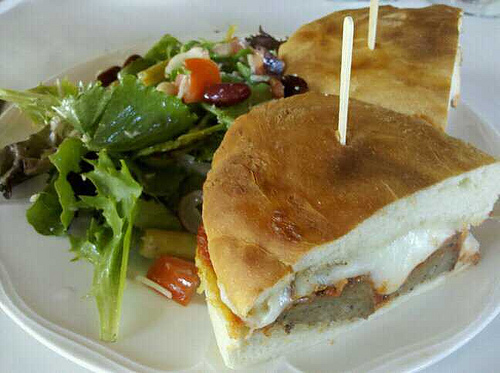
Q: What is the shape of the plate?
A: Circular.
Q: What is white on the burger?
A: Cheese.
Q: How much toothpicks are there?
A: Two.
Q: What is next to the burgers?
A: A salad.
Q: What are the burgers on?
A: A white plate.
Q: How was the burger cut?
A: In half.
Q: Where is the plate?
A: On a white surface.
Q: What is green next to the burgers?
A: Lettuce.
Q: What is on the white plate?
A: A burger and salad.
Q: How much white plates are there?
A: One.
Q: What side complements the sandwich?
A: A salad.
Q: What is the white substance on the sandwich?
A: Cheese.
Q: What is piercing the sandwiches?
A: Toothpicks.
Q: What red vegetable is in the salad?
A: Tomatoes.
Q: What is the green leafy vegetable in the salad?
A: Lettuce.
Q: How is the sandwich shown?
A: Cut in two.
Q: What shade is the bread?
A: Brown.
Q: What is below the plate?
A: A table cloth.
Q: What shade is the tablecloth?
A: White.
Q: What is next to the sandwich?
A: Salad.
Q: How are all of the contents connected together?
A: By a toothpick inserted into them.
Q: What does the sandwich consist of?
A: Black meat and cheese.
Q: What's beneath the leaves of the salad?
A: Additional vegetables.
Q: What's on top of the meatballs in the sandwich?
A: Mozzarella cheese.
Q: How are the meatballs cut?
A: Into halves.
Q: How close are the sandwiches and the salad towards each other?
A: They're slightly touching each other.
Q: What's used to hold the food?
A: A ceramic plate.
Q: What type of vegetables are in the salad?
A: Lettuce, tomatoes, olives and string peas.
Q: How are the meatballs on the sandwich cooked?
A: Slightly above medium rare.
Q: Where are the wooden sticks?
A: In the middles of the sandwich halves.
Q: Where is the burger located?
A: Plate.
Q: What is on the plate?
A: Burger and salad.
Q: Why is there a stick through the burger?
A: Keep it together.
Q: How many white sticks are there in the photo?
A: Two.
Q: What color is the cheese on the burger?
A: White.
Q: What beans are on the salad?
A: Red kidney beans.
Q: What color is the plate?
A: White.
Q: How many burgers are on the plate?
A: One.